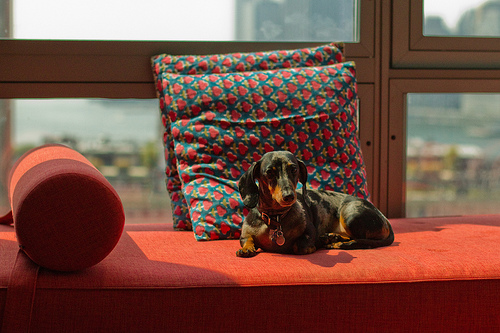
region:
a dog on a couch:
[25, 12, 495, 314]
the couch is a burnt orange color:
[17, 7, 489, 315]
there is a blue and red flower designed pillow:
[155, 55, 374, 254]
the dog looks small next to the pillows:
[158, 57, 402, 244]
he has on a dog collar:
[253, 207, 298, 247]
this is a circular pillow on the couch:
[5, 132, 140, 275]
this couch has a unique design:
[20, 58, 492, 290]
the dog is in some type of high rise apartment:
[25, 8, 496, 223]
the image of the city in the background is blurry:
[76, 108, 498, 244]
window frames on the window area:
[13, 18, 499, 112]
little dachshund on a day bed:
[228, 138, 402, 262]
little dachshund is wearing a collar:
[251, 193, 296, 249]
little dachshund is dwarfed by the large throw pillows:
[144, 31, 384, 251]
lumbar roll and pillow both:
[3, 135, 130, 284]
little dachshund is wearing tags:
[262, 221, 289, 249]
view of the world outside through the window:
[5, 6, 499, 225]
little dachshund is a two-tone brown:
[233, 142, 404, 260]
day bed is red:
[0, 138, 497, 330]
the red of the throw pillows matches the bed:
[147, 33, 386, 250]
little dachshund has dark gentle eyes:
[258, 158, 304, 183]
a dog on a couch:
[226, 147, 396, 269]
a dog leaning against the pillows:
[144, 48, 394, 263]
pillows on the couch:
[138, 48, 377, 242]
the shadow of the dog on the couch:
[271, 247, 376, 280]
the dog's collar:
[250, 200, 300, 251]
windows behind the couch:
[2, 0, 492, 231]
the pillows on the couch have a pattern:
[140, 41, 377, 248]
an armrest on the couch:
[1, 137, 153, 312]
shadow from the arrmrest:
[5, 165, 148, 285]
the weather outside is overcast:
[0, 0, 498, 219]